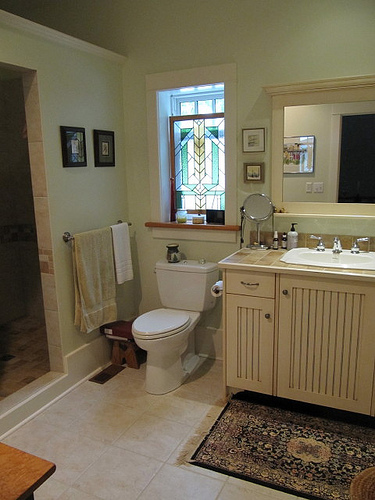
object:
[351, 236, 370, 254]
faucet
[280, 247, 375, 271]
sink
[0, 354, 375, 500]
floor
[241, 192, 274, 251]
mirror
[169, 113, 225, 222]
window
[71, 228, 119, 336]
towel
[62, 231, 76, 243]
towel rack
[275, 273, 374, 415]
door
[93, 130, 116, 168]
frame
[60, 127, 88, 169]
frame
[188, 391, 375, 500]
rug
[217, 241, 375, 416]
counter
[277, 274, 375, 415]
cabinet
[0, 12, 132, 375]
wall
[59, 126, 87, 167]
picture